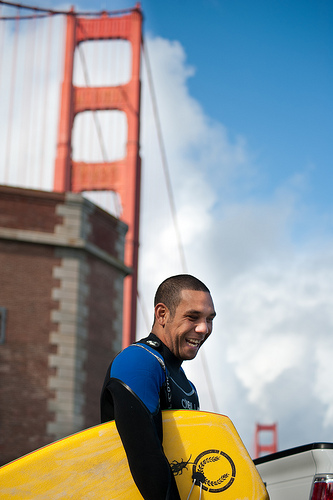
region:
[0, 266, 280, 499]
person carrying a surfboard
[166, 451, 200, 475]
black logo on a surfboard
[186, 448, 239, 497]
black logo on a surfboard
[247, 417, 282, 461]
red support of a bridge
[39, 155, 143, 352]
red support of a bridge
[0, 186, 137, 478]
wall made of bricks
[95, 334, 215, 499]
black and blue wet suit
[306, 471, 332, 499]
tail light of a truck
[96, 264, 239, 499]
man with short hair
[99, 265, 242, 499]
man holding yellow surfboard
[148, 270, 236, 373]
The man is laughing.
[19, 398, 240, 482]
The man is carrying a yellow surfboard.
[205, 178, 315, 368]
The sky is cloudy and blue.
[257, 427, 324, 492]
The truck is white.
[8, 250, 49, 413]
The bridge is brick.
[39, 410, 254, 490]
The surfboard is yellow.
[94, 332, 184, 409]
The swimsuit is blue and black.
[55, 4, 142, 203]
The bridge is orange.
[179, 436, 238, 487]
The surfboard has a black logo.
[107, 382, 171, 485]
The wetsuit has long black sleeves.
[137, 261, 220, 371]
person is smiling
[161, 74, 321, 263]
sky partially cloudy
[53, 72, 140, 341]
bridge is painted red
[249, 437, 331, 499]
white truck behind person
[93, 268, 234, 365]
man with very short hair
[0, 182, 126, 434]
structure made of bricks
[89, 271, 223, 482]
man wearing blue and black combination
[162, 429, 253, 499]
black printed symbols on surfboard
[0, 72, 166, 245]
bridge table holding with cables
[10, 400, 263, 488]
the surfboard is yellow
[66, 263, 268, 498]
the man is holding a surfboard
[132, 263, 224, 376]
the man is smiling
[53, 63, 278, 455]
there is a bridge in the background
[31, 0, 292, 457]
the bridge is orange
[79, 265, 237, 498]
the man is wearing a wetsuit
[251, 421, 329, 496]
the car is white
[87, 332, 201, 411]
the wetsuit is black and blue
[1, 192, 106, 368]
the building is behind the man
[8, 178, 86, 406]
the building is made of bricks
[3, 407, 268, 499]
the yellow boogie board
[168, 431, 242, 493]
the black design under the board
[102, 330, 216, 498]
the black and blue wet suit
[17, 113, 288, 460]
the golden gate bridge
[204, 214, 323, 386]
the clouds in the sky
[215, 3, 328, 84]
the clear blue sky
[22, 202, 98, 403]
the brick building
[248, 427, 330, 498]
the bed of a white truck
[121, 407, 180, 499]
the black part on the sleeve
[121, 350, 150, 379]
the blue on the wet suit